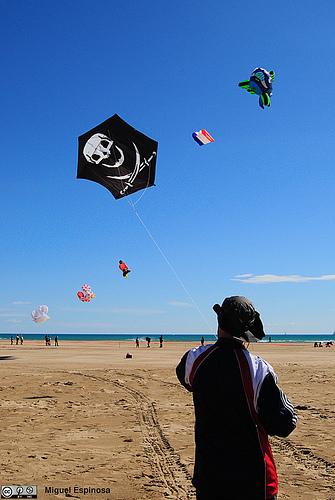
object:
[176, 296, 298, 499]
person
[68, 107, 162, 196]
candleskite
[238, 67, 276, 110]
kite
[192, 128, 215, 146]
kite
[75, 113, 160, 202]
kite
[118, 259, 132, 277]
kite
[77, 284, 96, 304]
kite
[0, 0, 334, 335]
sky